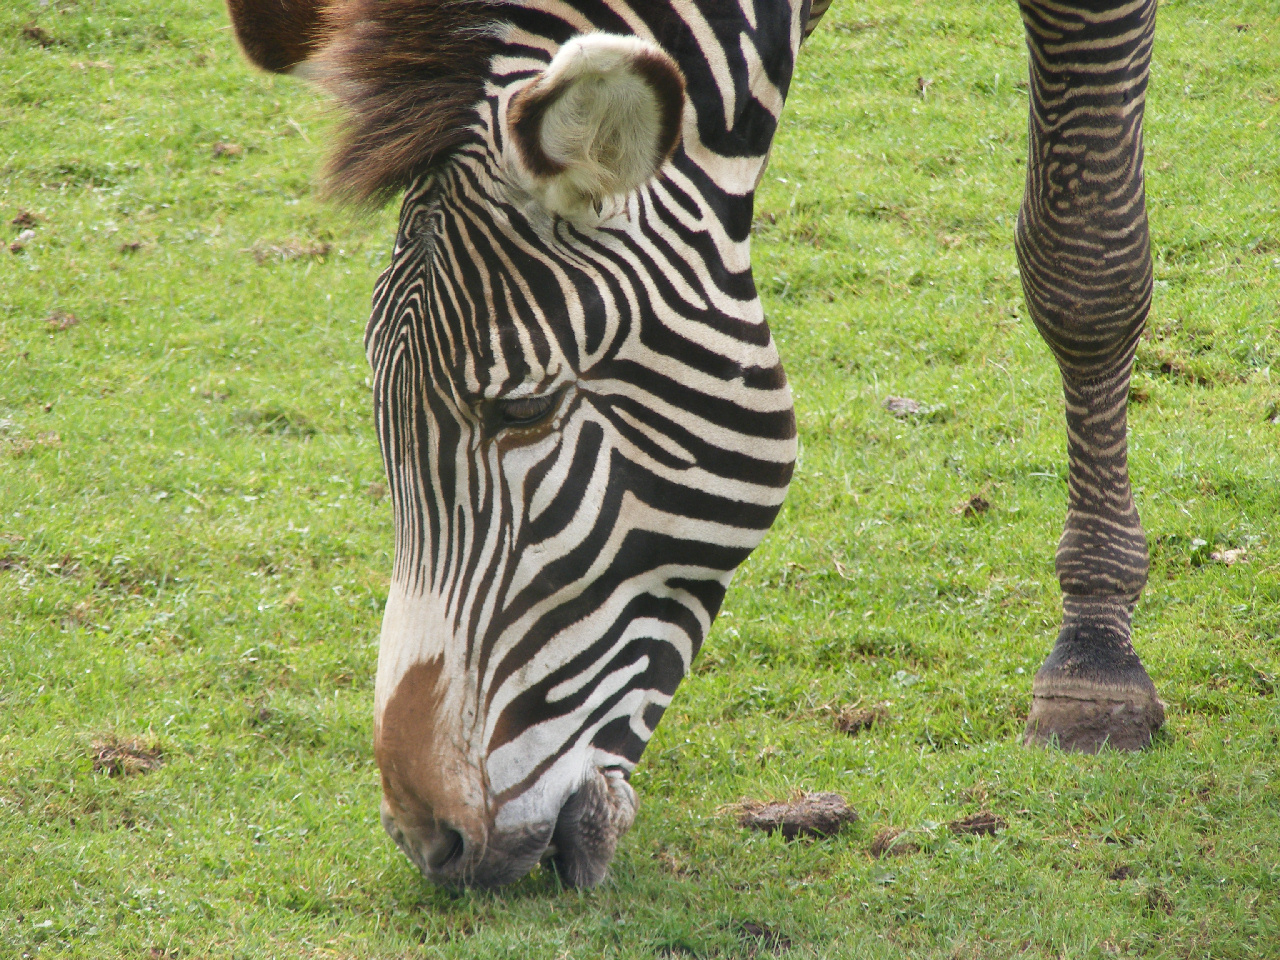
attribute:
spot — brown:
[372, 644, 448, 820]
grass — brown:
[735, 772, 876, 862]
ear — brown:
[477, 65, 581, 225]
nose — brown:
[339, 647, 483, 896]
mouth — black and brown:
[519, 765, 626, 911]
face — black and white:
[360, 486, 737, 762]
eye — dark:
[444, 344, 597, 472]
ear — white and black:
[486, 30, 688, 227]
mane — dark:
[288, 23, 497, 220]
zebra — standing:
[243, 23, 845, 867]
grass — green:
[652, 407, 1056, 923]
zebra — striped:
[254, 156, 777, 951]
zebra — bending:
[292, 107, 918, 909]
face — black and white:
[264, 118, 727, 774]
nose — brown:
[292, 663, 510, 830]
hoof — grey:
[1008, 651, 1217, 804]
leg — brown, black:
[985, 72, 1273, 567]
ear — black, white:
[471, 9, 827, 278]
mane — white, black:
[227, 37, 583, 190]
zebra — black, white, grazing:
[257, 139, 799, 851]